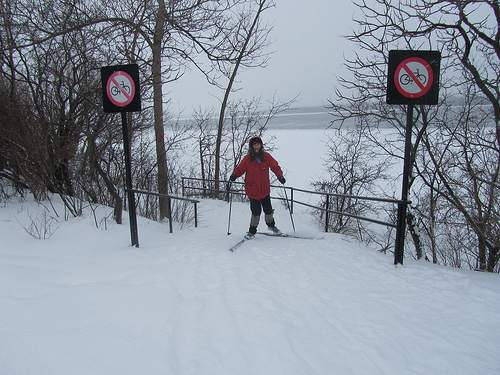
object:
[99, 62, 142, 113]
sign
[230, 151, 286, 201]
jacket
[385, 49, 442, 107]
sign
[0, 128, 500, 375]
snow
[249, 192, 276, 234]
pants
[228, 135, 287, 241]
woman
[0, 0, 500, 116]
sky